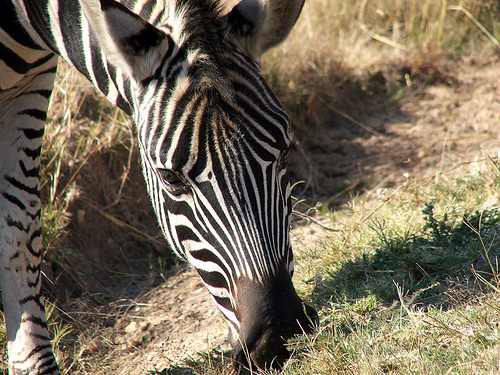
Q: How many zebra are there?
A: One.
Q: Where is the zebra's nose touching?
A: The ground.